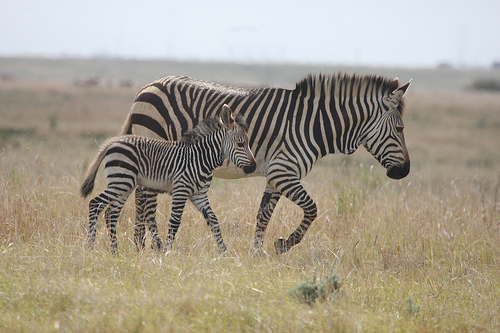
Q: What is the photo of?
A: Animals.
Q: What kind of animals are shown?
A: Zebras.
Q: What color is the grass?
A: Brown.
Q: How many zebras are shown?
A: Two.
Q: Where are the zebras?
A: Grasslands.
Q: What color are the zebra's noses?
A: Black.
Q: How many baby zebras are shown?
A: One.